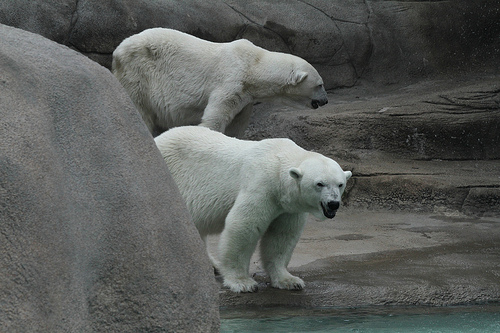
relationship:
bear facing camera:
[158, 116, 369, 296] [5, 314, 484, 331]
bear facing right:
[158, 116, 369, 296] [338, 222, 470, 325]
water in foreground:
[225, 301, 460, 330] [5, 213, 469, 332]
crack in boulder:
[314, 4, 378, 57] [1, 21, 234, 332]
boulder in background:
[330, 1, 478, 110] [2, 0, 481, 97]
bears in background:
[109, 25, 332, 134] [2, 0, 481, 97]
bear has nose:
[158, 116, 369, 296] [327, 197, 344, 215]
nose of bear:
[327, 197, 344, 215] [158, 116, 369, 296]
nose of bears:
[327, 197, 344, 215] [109, 25, 332, 134]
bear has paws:
[158, 116, 369, 296] [223, 263, 322, 303]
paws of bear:
[223, 263, 322, 303] [158, 116, 369, 296]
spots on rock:
[397, 122, 452, 178] [367, 72, 483, 240]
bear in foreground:
[158, 116, 369, 296] [5, 213, 469, 332]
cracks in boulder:
[225, 1, 383, 40] [1, 21, 234, 332]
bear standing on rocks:
[158, 116, 369, 296] [139, 214, 453, 292]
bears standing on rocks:
[99, 13, 358, 310] [139, 214, 453, 292]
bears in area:
[99, 13, 358, 310] [1, 1, 493, 324]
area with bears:
[1, 1, 493, 324] [99, 13, 358, 310]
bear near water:
[158, 116, 369, 296] [225, 301, 460, 330]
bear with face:
[158, 116, 369, 296] [310, 165, 353, 222]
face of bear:
[310, 165, 353, 222] [158, 116, 369, 296]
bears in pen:
[99, 13, 358, 310] [1, 1, 493, 324]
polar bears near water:
[99, 13, 358, 310] [225, 301, 460, 330]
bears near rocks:
[99, 13, 358, 310] [139, 214, 453, 292]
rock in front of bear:
[367, 72, 483, 240] [158, 116, 369, 296]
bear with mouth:
[158, 116, 369, 296] [321, 200, 340, 225]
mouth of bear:
[321, 200, 340, 225] [158, 116, 369, 296]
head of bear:
[290, 150, 364, 224] [158, 116, 369, 296]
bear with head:
[158, 116, 369, 296] [290, 150, 364, 224]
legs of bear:
[220, 186, 306, 295] [158, 116, 369, 296]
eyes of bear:
[314, 176, 346, 193] [158, 116, 369, 296]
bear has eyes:
[158, 116, 369, 296] [314, 176, 346, 193]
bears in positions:
[99, 13, 358, 310] [188, 36, 354, 293]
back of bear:
[149, 26, 221, 88] [158, 116, 369, 296]